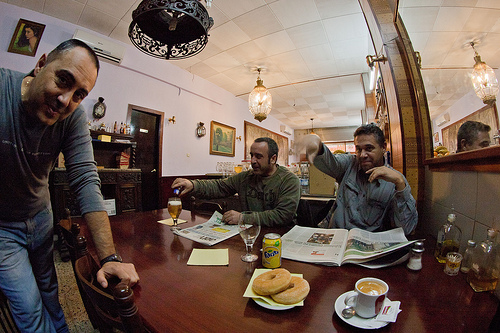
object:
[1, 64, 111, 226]
shirt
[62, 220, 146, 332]
chair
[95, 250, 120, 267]
wrist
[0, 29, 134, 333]
man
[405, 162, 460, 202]
ground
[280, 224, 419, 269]
newspaper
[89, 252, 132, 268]
watch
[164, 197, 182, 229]
glass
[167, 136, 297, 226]
man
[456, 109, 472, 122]
ground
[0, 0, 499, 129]
ceiling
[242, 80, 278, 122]
light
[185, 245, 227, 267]
napkin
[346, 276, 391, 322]
cup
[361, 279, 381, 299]
coffee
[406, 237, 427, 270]
shaker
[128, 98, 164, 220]
door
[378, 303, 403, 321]
sugar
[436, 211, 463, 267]
glass bottle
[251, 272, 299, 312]
plate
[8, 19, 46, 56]
painting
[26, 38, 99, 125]
head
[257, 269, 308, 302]
bagel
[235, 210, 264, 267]
empty glass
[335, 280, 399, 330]
coffee dish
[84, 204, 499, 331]
table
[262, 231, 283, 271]
can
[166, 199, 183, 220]
beer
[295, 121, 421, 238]
man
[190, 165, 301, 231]
shirt